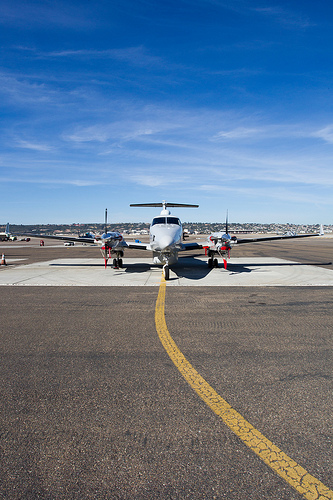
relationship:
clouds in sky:
[132, 155, 330, 192] [0, 2, 332, 224]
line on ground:
[156, 274, 330, 500] [0, 236, 332, 499]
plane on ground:
[13, 201, 322, 279] [0, 236, 332, 499]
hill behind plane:
[2, 222, 150, 241] [13, 201, 322, 279]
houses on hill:
[234, 224, 331, 235] [2, 222, 150, 241]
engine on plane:
[208, 231, 233, 250] [13, 201, 322, 279]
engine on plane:
[101, 231, 125, 249] [13, 201, 322, 279]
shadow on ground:
[170, 252, 211, 279] [0, 236, 332, 499]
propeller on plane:
[101, 207, 109, 270] [13, 201, 322, 279]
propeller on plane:
[222, 209, 230, 266] [13, 201, 322, 279]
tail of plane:
[129, 201, 199, 210] [13, 201, 322, 279]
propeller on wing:
[222, 209, 230, 266] [181, 233, 322, 255]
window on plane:
[151, 216, 181, 228] [13, 201, 322, 279]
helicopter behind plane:
[77, 228, 99, 241] [13, 201, 322, 279]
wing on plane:
[11, 231, 147, 249] [13, 201, 322, 279]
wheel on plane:
[163, 264, 172, 278] [13, 201, 322, 279]